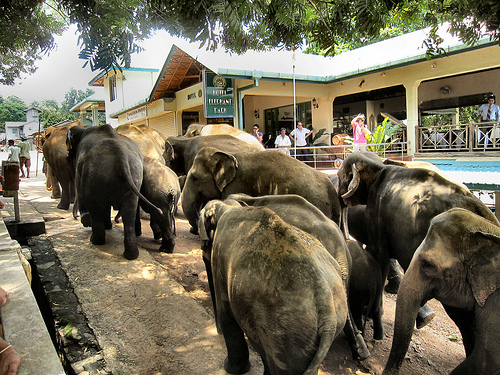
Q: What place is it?
A: It is a street.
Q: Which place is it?
A: It is a street.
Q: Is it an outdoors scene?
A: Yes, it is outdoors.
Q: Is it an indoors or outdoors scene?
A: It is outdoors.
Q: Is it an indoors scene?
A: No, it is outdoors.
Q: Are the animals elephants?
A: Yes, all the animals are elephants.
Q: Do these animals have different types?
A: No, all the animals are elephants.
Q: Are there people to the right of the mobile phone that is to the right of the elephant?
A: Yes, there is a person to the right of the mobile phone.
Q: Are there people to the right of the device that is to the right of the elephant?
A: Yes, there is a person to the right of the mobile phone.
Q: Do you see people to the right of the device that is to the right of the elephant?
A: Yes, there is a person to the right of the mobile phone.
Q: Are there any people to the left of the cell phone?
A: No, the person is to the right of the cell phone.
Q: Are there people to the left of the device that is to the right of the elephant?
A: No, the person is to the right of the cell phone.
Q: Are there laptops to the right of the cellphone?
A: No, there is a person to the right of the cellphone.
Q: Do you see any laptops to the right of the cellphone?
A: No, there is a person to the right of the cellphone.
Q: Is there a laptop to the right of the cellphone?
A: No, there is a person to the right of the cellphone.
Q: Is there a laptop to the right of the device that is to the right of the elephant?
A: No, there is a person to the right of the cellphone.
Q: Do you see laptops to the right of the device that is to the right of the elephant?
A: No, there is a person to the right of the cellphone.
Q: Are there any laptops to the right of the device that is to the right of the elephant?
A: No, there is a person to the right of the cellphone.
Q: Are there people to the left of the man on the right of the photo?
A: Yes, there is a person to the left of the man.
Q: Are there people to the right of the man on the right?
A: No, the person is to the left of the man.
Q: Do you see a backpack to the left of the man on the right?
A: No, there is a person to the left of the man.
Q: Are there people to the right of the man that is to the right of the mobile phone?
A: Yes, there is a person to the right of the man.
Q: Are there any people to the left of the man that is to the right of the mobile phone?
A: No, the person is to the right of the man.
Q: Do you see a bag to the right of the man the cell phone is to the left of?
A: No, there is a person to the right of the man.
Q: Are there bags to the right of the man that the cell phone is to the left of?
A: No, there is a person to the right of the man.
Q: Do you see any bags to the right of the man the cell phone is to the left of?
A: No, there is a person to the right of the man.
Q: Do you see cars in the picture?
A: No, there are no cars.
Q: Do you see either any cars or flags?
A: No, there are no cars or flags.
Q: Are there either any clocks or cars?
A: No, there are no cars or clocks.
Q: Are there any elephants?
A: Yes, there is an elephant.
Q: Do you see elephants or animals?
A: Yes, there is an elephant.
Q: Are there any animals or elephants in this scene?
A: Yes, there is an elephant.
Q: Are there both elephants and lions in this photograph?
A: No, there is an elephant but no lions.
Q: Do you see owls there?
A: No, there are no owls.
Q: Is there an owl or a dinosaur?
A: No, there are no owls or dinosaurs.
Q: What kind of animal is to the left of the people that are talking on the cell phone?
A: The animal is an elephant.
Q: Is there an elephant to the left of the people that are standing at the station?
A: Yes, there is an elephant to the left of the people.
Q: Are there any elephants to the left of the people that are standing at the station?
A: Yes, there is an elephant to the left of the people.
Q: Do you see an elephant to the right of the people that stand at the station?
A: No, the elephant is to the left of the people.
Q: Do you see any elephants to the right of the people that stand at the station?
A: No, the elephant is to the left of the people.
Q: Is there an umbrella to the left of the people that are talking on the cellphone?
A: No, there is an elephant to the left of the people.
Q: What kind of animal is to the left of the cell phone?
A: The animal is an elephant.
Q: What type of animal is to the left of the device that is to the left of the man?
A: The animal is an elephant.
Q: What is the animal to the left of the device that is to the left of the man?
A: The animal is an elephant.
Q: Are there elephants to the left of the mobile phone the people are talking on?
A: Yes, there is an elephant to the left of the cellphone.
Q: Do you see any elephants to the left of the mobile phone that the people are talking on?
A: Yes, there is an elephant to the left of the cellphone.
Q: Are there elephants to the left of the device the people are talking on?
A: Yes, there is an elephant to the left of the cellphone.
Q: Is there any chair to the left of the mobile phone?
A: No, there is an elephant to the left of the mobile phone.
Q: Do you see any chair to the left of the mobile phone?
A: No, there is an elephant to the left of the mobile phone.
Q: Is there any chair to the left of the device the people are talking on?
A: No, there is an elephant to the left of the mobile phone.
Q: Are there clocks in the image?
A: No, there are no clocks.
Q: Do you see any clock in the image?
A: No, there are no clocks.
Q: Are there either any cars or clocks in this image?
A: No, there are no clocks or cars.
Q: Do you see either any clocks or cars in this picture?
A: No, there are no clocks or cars.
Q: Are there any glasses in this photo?
A: No, there are no glasses.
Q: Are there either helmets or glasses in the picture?
A: No, there are no glasses or helmets.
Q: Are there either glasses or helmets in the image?
A: No, there are no glasses or helmets.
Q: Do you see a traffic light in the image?
A: No, there are no traffic lights.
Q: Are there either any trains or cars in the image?
A: No, there are no cars or trains.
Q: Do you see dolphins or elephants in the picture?
A: Yes, there is an elephant.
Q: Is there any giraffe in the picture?
A: No, there are no giraffes.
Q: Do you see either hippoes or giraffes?
A: No, there are no giraffes or hippoes.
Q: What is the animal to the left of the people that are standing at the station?
A: The animal is an elephant.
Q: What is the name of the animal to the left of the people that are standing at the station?
A: The animal is an elephant.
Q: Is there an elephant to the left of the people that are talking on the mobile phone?
A: Yes, there is an elephant to the left of the people.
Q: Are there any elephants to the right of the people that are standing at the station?
A: No, the elephant is to the left of the people.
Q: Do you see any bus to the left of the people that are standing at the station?
A: No, there is an elephant to the left of the people.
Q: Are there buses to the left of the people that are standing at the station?
A: No, there is an elephant to the left of the people.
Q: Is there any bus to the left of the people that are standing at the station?
A: No, there is an elephant to the left of the people.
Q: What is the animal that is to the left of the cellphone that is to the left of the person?
A: The animal is an elephant.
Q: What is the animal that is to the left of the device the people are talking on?
A: The animal is an elephant.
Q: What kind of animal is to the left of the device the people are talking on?
A: The animal is an elephant.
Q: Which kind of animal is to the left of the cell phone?
A: The animal is an elephant.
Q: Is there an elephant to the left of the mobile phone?
A: Yes, there is an elephant to the left of the mobile phone.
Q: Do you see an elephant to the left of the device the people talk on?
A: Yes, there is an elephant to the left of the mobile phone.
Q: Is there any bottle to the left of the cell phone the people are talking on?
A: No, there is an elephant to the left of the cellphone.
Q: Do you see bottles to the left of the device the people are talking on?
A: No, there is an elephant to the left of the cellphone.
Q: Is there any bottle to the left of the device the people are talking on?
A: No, there is an elephant to the left of the cellphone.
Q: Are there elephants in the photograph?
A: Yes, there is an elephant.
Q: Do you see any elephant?
A: Yes, there is an elephant.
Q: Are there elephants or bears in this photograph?
A: Yes, there is an elephant.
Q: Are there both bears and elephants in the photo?
A: No, there is an elephant but no bears.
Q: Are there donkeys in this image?
A: No, there are no donkeys.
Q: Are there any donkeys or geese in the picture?
A: No, there are no donkeys or geese.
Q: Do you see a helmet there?
A: No, there are no helmets.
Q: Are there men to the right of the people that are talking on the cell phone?
A: Yes, there is a man to the right of the people.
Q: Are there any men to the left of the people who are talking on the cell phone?
A: No, the man is to the right of the people.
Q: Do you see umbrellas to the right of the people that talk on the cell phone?
A: No, there is a man to the right of the people.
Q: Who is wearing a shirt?
A: The man is wearing a shirt.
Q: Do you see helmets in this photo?
A: No, there are no helmets.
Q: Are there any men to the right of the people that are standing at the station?
A: Yes, there is a man to the right of the people.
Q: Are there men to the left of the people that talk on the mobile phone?
A: No, the man is to the right of the people.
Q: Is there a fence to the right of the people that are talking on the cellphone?
A: No, there is a man to the right of the people.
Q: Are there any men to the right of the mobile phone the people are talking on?
A: Yes, there is a man to the right of the cellphone.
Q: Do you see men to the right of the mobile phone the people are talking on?
A: Yes, there is a man to the right of the cellphone.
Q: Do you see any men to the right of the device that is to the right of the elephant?
A: Yes, there is a man to the right of the cellphone.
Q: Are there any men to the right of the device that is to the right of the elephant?
A: Yes, there is a man to the right of the cellphone.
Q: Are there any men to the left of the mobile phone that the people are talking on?
A: No, the man is to the right of the cellphone.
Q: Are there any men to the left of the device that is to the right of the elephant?
A: No, the man is to the right of the cellphone.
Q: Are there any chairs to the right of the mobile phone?
A: No, there is a man to the right of the mobile phone.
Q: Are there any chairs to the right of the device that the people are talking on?
A: No, there is a man to the right of the mobile phone.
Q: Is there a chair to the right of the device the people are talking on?
A: No, there is a man to the right of the mobile phone.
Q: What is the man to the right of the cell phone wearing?
A: The man is wearing a shirt.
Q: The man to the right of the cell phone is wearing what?
A: The man is wearing a shirt.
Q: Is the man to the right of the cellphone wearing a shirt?
A: Yes, the man is wearing a shirt.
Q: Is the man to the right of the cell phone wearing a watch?
A: No, the man is wearing a shirt.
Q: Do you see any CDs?
A: No, there are no cds.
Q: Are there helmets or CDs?
A: No, there are no CDs or helmets.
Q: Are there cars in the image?
A: No, there are no cars.